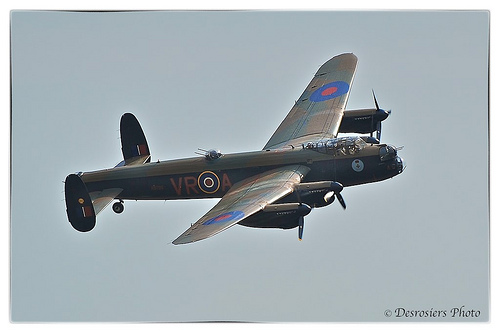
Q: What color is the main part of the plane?
A: Green.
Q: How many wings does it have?
A: 2.